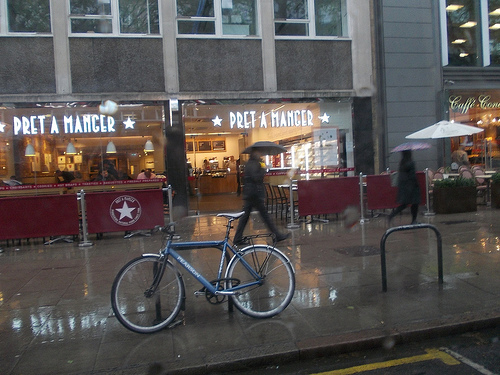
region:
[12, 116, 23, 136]
white letter on sign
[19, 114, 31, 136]
white letter on sign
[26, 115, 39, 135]
white letter on sign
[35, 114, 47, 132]
white letter on sign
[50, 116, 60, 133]
white letter on sign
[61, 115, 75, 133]
white letter on sign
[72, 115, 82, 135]
white letter on sign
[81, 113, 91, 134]
white letter on sign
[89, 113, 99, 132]
white letter on sign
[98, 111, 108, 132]
white letter on sign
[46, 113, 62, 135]
white letter on sign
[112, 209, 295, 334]
black and blue bicycloe on street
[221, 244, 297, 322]
big black back wheel of bicycle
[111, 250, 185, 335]
big black front wheel of bicycle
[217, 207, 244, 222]
littl black seat of bicycle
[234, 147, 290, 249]
man walking on sidewalk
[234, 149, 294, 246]
man wearing bloack leather jacket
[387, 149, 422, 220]
woman waling by sidewalk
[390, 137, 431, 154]
purple umbrella of woman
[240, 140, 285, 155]
black umbrella of man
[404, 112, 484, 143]
white umbrella of restaurant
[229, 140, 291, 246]
Man walking with an umbrella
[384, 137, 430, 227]
Woman walking under an umbrella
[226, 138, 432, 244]
Two people holding umbrellas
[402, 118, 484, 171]
Large white patio umbrella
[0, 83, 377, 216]
Restaurant with white letter signs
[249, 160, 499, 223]
Outdoor table and chair sets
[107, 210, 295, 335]
Blue bicycle parked on a sidewalk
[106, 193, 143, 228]
Circle and star logo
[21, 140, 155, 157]
Four white ceiling lamps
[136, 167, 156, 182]
Man wearing a pink shirt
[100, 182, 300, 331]
a blue bike in the foreground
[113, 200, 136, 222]
a white star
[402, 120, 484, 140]
a white umbrella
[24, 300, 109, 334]
light reflected on the ground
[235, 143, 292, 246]
a man carrying an ummbrella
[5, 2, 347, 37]
some crystal winndows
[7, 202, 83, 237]
this wall is red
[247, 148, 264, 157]
the head of the man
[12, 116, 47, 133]
the word PRET in white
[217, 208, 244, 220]
the bike seat